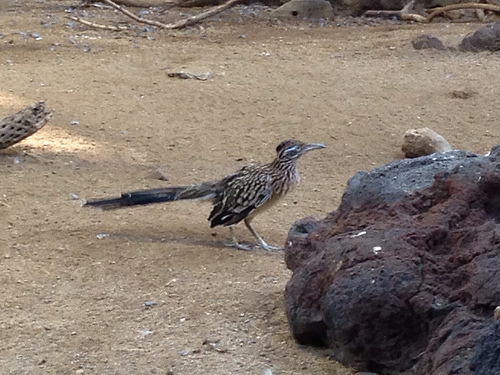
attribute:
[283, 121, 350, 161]
beak — pointed and yellow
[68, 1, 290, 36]
branch — dead and broken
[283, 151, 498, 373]
rock — two and dark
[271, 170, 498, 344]
rock — brown and gray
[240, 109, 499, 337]
rock — large and gray 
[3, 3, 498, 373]
beach — sandy,rocky and tan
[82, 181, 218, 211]
tail — long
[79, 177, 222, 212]
tailfeather — long and black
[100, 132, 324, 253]
feathers — colorful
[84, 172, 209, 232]
feathers — long